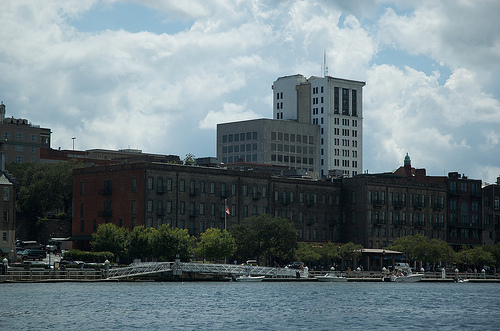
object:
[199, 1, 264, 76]
sky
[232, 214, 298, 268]
bush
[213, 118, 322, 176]
building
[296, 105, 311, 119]
wall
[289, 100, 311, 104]
wall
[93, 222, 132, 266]
bush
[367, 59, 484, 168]
clouds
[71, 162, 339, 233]
bulding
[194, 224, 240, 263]
bush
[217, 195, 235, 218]
flag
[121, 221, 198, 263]
bush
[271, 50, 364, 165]
building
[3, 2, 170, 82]
sky